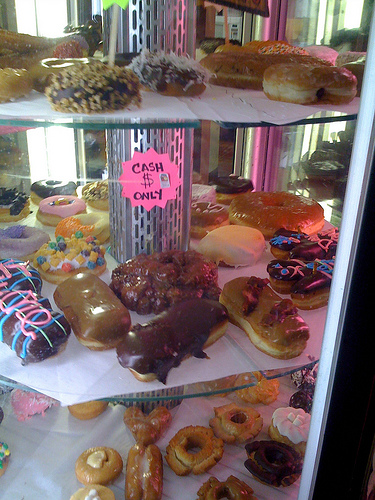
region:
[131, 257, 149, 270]
part of a glass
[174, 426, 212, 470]
Round brown donut on display.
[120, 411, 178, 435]
Heart shaped donut on display.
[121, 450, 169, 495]
Long glazed donut on display.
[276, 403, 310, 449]
White frosting on top of donut.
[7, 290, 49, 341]
Pink and blue frosting on display.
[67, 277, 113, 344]
Chocolate frosting on donut.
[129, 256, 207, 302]
Large brown donut on display.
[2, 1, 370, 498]
large carousel display case filled with various donuts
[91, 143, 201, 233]
small pink sign reading cash only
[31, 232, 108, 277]
donut with white icing and cereal on top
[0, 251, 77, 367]
donut with pink and blue icing on top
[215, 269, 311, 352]
long john donut with maple icing and bacon on top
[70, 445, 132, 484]
round donut with glaze and cream cheese icing on top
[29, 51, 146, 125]
chocolate covered donut with nuts on top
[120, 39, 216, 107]
cake donut with chocolate icing and coconut on top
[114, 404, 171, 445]
heart shaped glazed donut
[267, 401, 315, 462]
round donut with white and pink icing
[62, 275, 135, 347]
the maple bar doughnut in the case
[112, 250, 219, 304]
the apple frittar on the wax paper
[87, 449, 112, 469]
the cream in the doughnut center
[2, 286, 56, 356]
the pink and blue icing on the doughnut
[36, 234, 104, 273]
the captain crunch cereal on the doughnut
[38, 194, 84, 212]
the pink doughnut frosting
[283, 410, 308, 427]
the three marshmellows in the doughnut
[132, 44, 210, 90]
the coconut flakes on the chocolate doughnut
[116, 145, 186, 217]
the pink sign on the case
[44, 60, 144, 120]
the gound nuts on the doughnut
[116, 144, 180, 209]
Pink signs says 'cash only'.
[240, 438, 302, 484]
Fried doughnut with chocolate glaze.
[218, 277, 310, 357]
Maple eclair with strips of chocolate.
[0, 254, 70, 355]
Long chocolate covered doughnut with pink and blue.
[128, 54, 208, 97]
Baked doughnut with chocolate icing and coconut flakes.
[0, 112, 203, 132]
Edge of glass shelf for doughnuts.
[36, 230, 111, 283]
Glazed with white frosting doughnut and captain crunch atop.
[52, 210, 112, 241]
Doughnut with orange glazed and sprinkles.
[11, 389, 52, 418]
Pink doughnut with coconut flakes.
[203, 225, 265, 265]
Doughnut covered with white frosting.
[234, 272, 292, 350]
a donut on display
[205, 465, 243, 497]
a donut on display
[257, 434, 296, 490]
a donut on display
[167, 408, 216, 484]
a donut on display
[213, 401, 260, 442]
a donut on display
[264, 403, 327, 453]
a donut on display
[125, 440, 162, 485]
a donut on display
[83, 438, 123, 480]
a donut on display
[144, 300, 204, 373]
a donut on display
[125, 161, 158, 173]
cash on the sign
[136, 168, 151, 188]
dollar sign on the sign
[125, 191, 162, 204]
only on the sign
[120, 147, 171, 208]
sign on the pole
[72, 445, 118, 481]
pastry on the tray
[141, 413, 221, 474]
donut on the tray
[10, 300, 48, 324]
frosting on the pastry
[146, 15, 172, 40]
the pole is silver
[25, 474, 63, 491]
the paper is white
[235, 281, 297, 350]
bar on the tray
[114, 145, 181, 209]
The sign says Cash Only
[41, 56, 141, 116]
The chocolate doughnut is covered with nuts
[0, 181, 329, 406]
A sheet of wax paper protects the glass